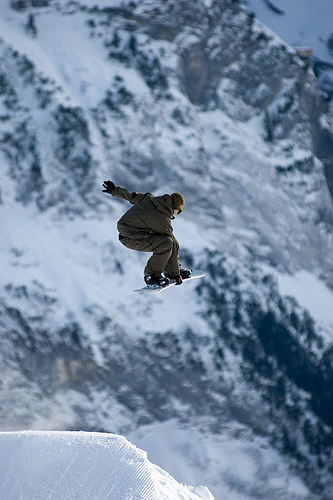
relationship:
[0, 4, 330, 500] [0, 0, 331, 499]
snow on side of mountain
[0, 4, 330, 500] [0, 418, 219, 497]
snow on side of mountain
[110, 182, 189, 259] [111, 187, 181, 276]
sweater with sweater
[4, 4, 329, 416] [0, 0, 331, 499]
snow on side of mountain